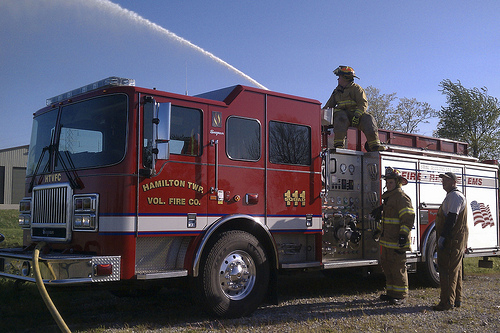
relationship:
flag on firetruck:
[467, 200, 497, 230] [4, 76, 493, 316]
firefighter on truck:
[322, 65, 386, 151] [2, 74, 499, 322]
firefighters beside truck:
[313, 40, 495, 315] [2, 74, 499, 322]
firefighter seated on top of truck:
[325, 64, 383, 152] [2, 74, 499, 322]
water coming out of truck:
[79, 1, 276, 88] [2, 74, 499, 322]